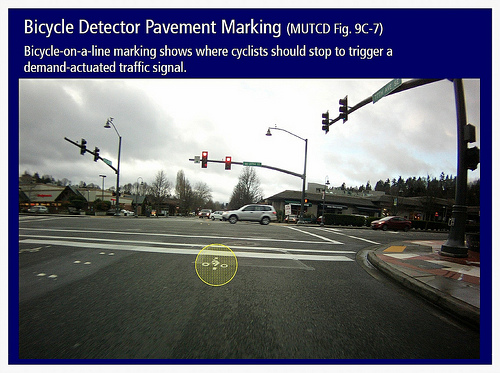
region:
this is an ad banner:
[4, 3, 496, 85]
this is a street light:
[215, 153, 238, 186]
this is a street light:
[91, 118, 118, 141]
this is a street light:
[91, 141, 107, 168]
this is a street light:
[69, 127, 96, 175]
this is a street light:
[311, 101, 326, 123]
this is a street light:
[327, 96, 357, 143]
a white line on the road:
[101, 214, 377, 314]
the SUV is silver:
[216, 190, 302, 238]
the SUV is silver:
[202, 192, 293, 249]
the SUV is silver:
[195, 189, 301, 247]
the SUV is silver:
[192, 182, 287, 230]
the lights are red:
[185, 142, 239, 167]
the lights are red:
[190, 137, 241, 177]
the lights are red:
[190, 146, 243, 184]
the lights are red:
[192, 140, 246, 182]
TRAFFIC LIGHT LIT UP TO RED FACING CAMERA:
[199, 147, 209, 168]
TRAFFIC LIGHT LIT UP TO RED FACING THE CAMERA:
[222, 154, 234, 169]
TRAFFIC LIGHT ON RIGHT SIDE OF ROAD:
[334, 94, 350, 124]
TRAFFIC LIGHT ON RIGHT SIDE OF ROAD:
[320, 108, 331, 133]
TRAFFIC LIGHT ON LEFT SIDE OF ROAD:
[77, 134, 89, 157]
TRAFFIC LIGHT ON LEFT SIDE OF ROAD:
[94, 144, 101, 163]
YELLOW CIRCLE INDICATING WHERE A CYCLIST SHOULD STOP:
[191, 239, 244, 291]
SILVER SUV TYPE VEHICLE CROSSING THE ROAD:
[218, 197, 281, 229]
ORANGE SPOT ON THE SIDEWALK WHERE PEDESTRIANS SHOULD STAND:
[384, 242, 406, 253]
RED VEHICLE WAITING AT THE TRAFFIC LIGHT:
[366, 214, 412, 231]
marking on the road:
[89, 234, 107, 248]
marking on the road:
[161, 228, 181, 275]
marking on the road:
[254, 253, 294, 266]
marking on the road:
[321, 244, 354, 269]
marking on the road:
[271, 231, 298, 253]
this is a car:
[211, 203, 277, 222]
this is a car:
[365, 214, 417, 231]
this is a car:
[27, 199, 47, 219]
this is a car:
[199, 204, 211, 219]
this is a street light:
[216, 146, 249, 182]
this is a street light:
[188, 140, 215, 173]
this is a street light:
[316, 105, 336, 138]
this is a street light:
[326, 86, 352, 143]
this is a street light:
[71, 123, 95, 172]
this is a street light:
[98, 114, 119, 134]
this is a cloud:
[136, 103, 185, 169]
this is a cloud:
[226, 105, 266, 143]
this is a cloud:
[38, 80, 108, 160]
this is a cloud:
[231, 107, 301, 161]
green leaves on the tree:
[404, 173, 422, 191]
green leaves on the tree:
[429, 178, 444, 191]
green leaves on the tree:
[189, 187, 199, 214]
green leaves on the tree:
[326, 172, 353, 193]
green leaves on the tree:
[349, 181, 367, 197]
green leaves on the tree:
[374, 177, 393, 198]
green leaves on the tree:
[186, 187, 197, 205]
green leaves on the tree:
[171, 192, 189, 223]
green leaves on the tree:
[412, 176, 431, 191]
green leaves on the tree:
[423, 173, 444, 188]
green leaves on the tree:
[405, 181, 417, 191]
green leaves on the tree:
[440, 169, 458, 193]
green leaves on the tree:
[229, 176, 261, 204]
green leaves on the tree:
[187, 170, 212, 204]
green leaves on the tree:
[163, 178, 172, 188]